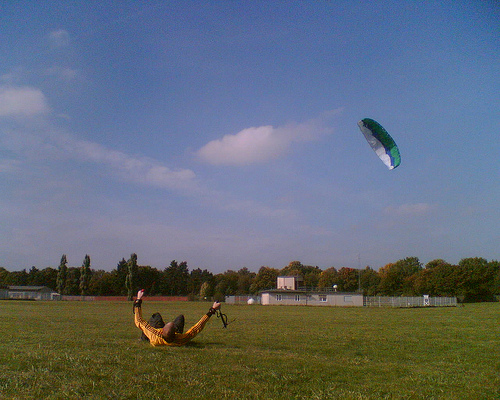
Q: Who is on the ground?
A: The person.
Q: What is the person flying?
A: A kite.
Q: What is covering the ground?
A: Grass.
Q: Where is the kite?
A: In the air.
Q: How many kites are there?
A: One.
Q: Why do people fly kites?
A: Recreation.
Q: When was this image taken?
A: Daytime.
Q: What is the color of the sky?
A: Blue.